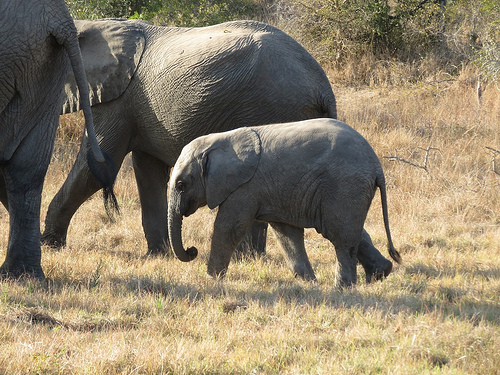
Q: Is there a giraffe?
A: No, there are no giraffes.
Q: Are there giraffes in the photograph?
A: No, there are no giraffes.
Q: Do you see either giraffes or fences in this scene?
A: No, there are no giraffes or fences.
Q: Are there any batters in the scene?
A: No, there are no batters.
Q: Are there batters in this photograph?
A: No, there are no batters.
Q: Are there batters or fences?
A: No, there are no batters or fences.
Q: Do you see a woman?
A: No, there are no women.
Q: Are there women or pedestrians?
A: No, there are no women or pedestrians.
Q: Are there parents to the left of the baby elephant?
A: Yes, there is a parent to the left of the elephant.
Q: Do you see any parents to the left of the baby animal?
A: Yes, there is a parent to the left of the elephant.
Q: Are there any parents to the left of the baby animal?
A: Yes, there is a parent to the left of the elephant.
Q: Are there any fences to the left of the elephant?
A: No, there is a parent to the left of the elephant.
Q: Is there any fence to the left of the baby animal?
A: No, there is a parent to the left of the elephant.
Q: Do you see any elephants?
A: Yes, there is an elephant.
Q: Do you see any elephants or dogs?
A: Yes, there is an elephant.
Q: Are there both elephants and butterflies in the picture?
A: No, there is an elephant but no butterflies.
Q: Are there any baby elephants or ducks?
A: Yes, there is a baby elephant.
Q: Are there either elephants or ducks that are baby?
A: Yes, the elephant is a baby.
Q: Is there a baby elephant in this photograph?
A: Yes, there is a baby elephant.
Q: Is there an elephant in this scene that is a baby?
A: Yes, there is an elephant that is a baby.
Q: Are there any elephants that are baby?
A: Yes, there is an elephant that is a baby.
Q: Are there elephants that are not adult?
A: Yes, there is an baby elephant.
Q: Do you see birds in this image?
A: No, there are no birds.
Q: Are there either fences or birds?
A: No, there are no birds or fences.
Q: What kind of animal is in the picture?
A: The animal is an elephant.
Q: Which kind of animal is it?
A: The animal is an elephant.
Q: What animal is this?
A: This is an elephant.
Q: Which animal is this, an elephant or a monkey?
A: This is an elephant.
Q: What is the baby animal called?
A: The animal is an elephant.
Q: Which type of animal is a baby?
A: The animal is an elephant.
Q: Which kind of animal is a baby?
A: The animal is an elephant.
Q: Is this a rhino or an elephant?
A: This is an elephant.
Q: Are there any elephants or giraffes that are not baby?
A: No, there is an elephant but it is a baby.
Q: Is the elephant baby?
A: Yes, the elephant is a baby.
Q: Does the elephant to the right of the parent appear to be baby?
A: Yes, the elephant is a baby.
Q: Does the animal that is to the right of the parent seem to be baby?
A: Yes, the elephant is a baby.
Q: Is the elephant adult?
A: No, the elephant is a baby.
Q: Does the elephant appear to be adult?
A: No, the elephant is a baby.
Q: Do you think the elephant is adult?
A: No, the elephant is a baby.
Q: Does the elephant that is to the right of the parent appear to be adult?
A: No, the elephant is a baby.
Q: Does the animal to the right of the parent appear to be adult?
A: No, the elephant is a baby.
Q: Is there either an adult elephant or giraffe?
A: No, there is an elephant but it is a baby.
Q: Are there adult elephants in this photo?
A: No, there is an elephant but it is a baby.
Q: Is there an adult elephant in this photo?
A: No, there is an elephant but it is a baby.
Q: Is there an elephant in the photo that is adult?
A: No, there is an elephant but it is a baby.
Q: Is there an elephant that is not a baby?
A: No, there is an elephant but it is a baby.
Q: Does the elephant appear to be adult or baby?
A: The elephant is a baby.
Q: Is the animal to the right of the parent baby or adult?
A: The elephant is a baby.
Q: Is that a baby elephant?
A: Yes, that is a baby elephant.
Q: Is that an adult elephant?
A: No, that is a baby elephant.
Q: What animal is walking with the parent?
A: The elephant is walking with the parent.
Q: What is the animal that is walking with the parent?
A: The animal is an elephant.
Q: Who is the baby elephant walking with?
A: The elephant is walking with a parent.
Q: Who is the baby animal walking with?
A: The elephant is walking with a parent.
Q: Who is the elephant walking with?
A: The elephant is walking with a parent.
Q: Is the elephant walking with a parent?
A: Yes, the elephant is walking with a parent.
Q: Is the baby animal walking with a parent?
A: Yes, the elephant is walking with a parent.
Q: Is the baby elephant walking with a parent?
A: Yes, the elephant is walking with a parent.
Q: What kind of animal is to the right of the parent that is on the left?
A: The animal is an elephant.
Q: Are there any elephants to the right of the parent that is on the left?
A: Yes, there is an elephant to the right of the parent.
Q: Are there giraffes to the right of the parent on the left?
A: No, there is an elephant to the right of the parent.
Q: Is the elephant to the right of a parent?
A: Yes, the elephant is to the right of a parent.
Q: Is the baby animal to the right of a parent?
A: Yes, the elephant is to the right of a parent.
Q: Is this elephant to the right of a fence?
A: No, the elephant is to the right of a parent.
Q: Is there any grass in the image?
A: Yes, there is grass.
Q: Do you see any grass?
A: Yes, there is grass.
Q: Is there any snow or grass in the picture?
A: Yes, there is grass.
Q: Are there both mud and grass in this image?
A: No, there is grass but no mud.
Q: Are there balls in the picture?
A: No, there are no balls.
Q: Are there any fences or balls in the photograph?
A: No, there are no balls or fences.